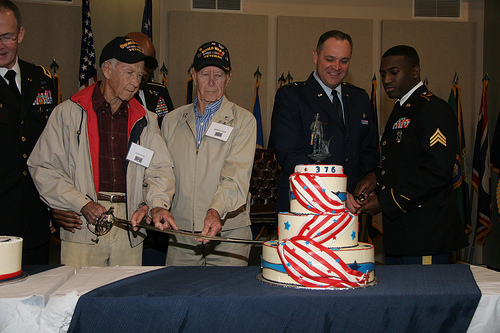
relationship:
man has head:
[156, 40, 257, 277] [189, 43, 232, 108]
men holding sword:
[27, 36, 257, 267] [92, 205, 264, 243]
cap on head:
[195, 39, 232, 74] [189, 43, 232, 108]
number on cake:
[313, 162, 339, 175] [258, 161, 378, 291]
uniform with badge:
[160, 91, 256, 266] [205, 117, 235, 145]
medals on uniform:
[391, 113, 413, 132] [377, 80, 471, 263]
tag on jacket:
[124, 141, 155, 170] [24, 76, 178, 246]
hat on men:
[96, 36, 160, 73] [26, 36, 265, 268]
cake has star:
[258, 161, 378, 291] [283, 216, 292, 230]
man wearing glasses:
[1, 2, 55, 263] [2, 31, 20, 43]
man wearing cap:
[156, 40, 257, 277] [193, 41, 231, 74]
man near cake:
[156, 40, 257, 277] [258, 161, 378, 291]